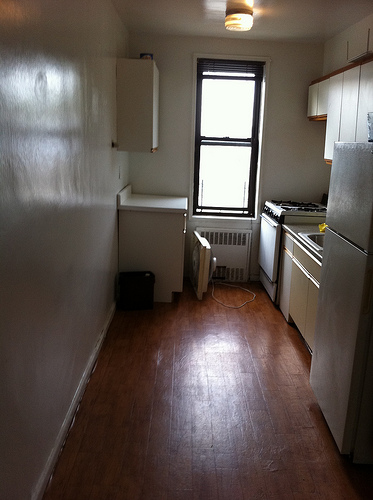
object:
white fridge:
[307, 141, 373, 463]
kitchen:
[0, 0, 373, 498]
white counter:
[119, 193, 188, 215]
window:
[196, 143, 252, 211]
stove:
[257, 199, 326, 304]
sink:
[296, 229, 324, 252]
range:
[255, 197, 323, 356]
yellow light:
[223, 12, 252, 31]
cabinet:
[354, 62, 373, 144]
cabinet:
[116, 59, 159, 151]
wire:
[211, 281, 257, 309]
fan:
[189, 228, 215, 302]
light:
[222, 12, 254, 32]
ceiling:
[113, 0, 373, 39]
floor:
[40, 279, 373, 497]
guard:
[199, 229, 251, 284]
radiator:
[196, 229, 253, 281]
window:
[198, 79, 256, 140]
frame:
[193, 144, 257, 217]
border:
[305, 109, 316, 121]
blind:
[202, 60, 262, 75]